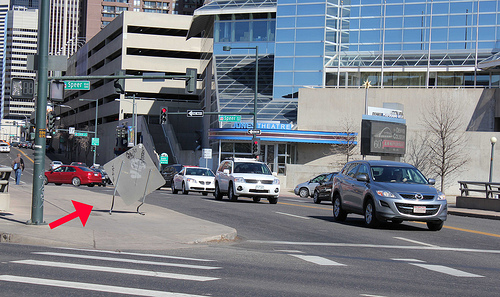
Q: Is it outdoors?
A: Yes, it is outdoors.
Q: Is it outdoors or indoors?
A: It is outdoors.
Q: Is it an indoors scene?
A: No, it is outdoors.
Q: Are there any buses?
A: No, there are no buses.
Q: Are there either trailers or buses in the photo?
A: No, there are no buses or trailers.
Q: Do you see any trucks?
A: No, there are no trucks.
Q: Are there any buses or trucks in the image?
A: No, there are no trucks or buses.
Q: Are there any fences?
A: No, there are no fences.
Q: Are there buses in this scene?
A: No, there are no buses.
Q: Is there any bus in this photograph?
A: No, there are no buses.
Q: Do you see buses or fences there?
A: No, there are no buses or fences.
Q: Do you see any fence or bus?
A: No, there are no buses or fences.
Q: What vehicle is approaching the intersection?
A: The vehicle is a car.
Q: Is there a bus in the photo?
A: No, there are no buses.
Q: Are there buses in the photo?
A: No, there are no buses.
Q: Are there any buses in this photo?
A: No, there are no buses.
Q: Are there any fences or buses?
A: No, there are no buses or fences.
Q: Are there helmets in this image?
A: No, there are no helmets.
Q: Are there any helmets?
A: No, there are no helmets.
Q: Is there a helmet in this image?
A: No, there are no helmets.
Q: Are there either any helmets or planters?
A: No, there are no helmets or planters.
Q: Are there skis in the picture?
A: No, there are no skis.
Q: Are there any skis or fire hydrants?
A: No, there are no skis or fire hydrants.